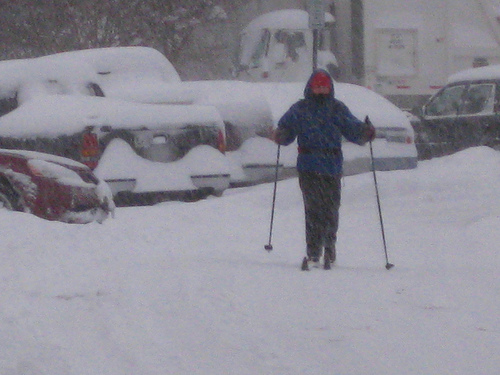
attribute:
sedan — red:
[1, 141, 145, 234]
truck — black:
[34, 83, 255, 184]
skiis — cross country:
[224, 205, 416, 294]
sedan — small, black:
[399, 60, 498, 154]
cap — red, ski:
[310, 69, 331, 87]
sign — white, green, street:
[303, 2, 323, 70]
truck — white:
[225, 8, 396, 103]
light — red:
[83, 125, 149, 185]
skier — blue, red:
[264, 60, 384, 274]